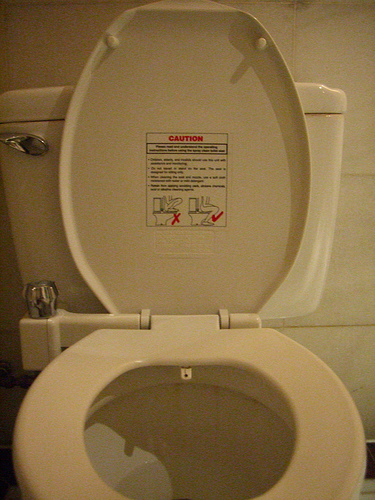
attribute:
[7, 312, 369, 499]
toilet seat — white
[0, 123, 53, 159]
flush knob — metallic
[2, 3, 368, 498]
toilet — white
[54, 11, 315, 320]
lid — up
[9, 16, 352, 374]
wall — white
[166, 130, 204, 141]
writing — red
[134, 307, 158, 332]
hinge — white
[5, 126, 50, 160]
handle — metal, flushing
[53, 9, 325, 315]
toilet lid — up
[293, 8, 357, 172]
tile — white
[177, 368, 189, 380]
metal — small piece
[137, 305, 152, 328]
hinge — plastic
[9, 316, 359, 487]
toilet seat — round, white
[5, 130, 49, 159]
handle — chrome, toilet, flush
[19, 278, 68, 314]
knob — chrome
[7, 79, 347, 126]
lid — white, ceramic, toilet tank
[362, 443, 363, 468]
trim — brown, floor, wall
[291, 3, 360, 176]
tile — yellow stained, white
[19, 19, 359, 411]
wall — bathroom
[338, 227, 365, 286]
tile — white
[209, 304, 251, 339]
hinge — white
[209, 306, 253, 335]
hinge — toilet seat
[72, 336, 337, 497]
toilet seat — white